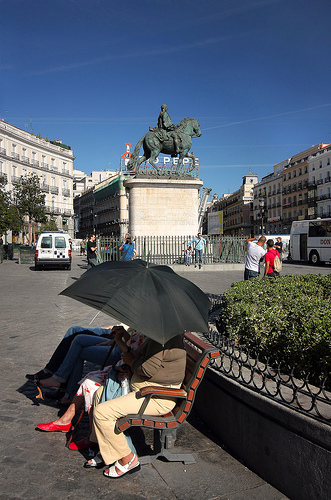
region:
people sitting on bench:
[30, 243, 228, 481]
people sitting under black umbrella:
[52, 248, 227, 368]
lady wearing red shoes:
[23, 399, 92, 468]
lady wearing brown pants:
[92, 359, 181, 495]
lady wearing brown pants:
[118, 326, 201, 399]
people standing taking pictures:
[224, 214, 291, 297]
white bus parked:
[278, 192, 330, 286]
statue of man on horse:
[125, 97, 211, 190]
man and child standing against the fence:
[178, 224, 218, 275]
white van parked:
[11, 222, 87, 288]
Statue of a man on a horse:
[124, 95, 226, 186]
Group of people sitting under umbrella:
[37, 265, 199, 462]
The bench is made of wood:
[174, 368, 216, 424]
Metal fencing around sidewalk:
[231, 343, 302, 415]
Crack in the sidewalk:
[209, 468, 261, 491]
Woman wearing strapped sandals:
[101, 445, 149, 479]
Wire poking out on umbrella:
[85, 309, 109, 352]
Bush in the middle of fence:
[250, 251, 327, 345]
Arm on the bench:
[124, 377, 213, 413]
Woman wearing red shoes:
[26, 410, 89, 454]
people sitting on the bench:
[25, 222, 219, 471]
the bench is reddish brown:
[51, 308, 222, 448]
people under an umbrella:
[45, 229, 219, 387]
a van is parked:
[16, 222, 80, 274]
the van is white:
[20, 215, 89, 284]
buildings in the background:
[209, 175, 323, 224]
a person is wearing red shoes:
[26, 405, 81, 451]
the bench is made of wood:
[117, 350, 221, 433]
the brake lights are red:
[23, 243, 76, 262]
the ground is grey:
[0, 252, 66, 328]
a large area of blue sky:
[0, 0, 330, 202]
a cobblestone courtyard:
[0, 250, 330, 498]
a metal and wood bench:
[115, 331, 222, 465]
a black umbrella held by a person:
[57, 252, 214, 346]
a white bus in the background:
[289, 216, 329, 264]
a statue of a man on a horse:
[126, 103, 201, 180]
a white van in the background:
[34, 232, 71, 268]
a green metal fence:
[95, 235, 251, 263]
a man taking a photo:
[243, 235, 265, 280]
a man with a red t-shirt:
[263, 238, 282, 275]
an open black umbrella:
[35, 240, 229, 353]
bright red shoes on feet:
[28, 411, 98, 455]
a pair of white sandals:
[86, 444, 159, 485]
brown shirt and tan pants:
[95, 339, 196, 468]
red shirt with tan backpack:
[256, 244, 290, 280]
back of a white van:
[25, 220, 88, 271]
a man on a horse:
[121, 86, 210, 181]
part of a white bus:
[280, 212, 330, 275]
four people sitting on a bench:
[44, 288, 236, 481]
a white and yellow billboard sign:
[201, 205, 240, 254]